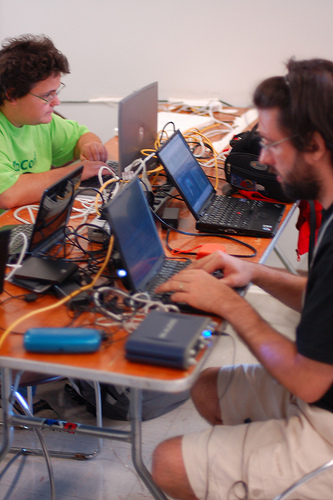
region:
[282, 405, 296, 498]
a man is wearing shorts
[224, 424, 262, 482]
a man is wearing shorts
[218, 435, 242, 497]
a man is wearing shorts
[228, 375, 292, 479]
a man is wearing shorts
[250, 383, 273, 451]
a man is wearing shorts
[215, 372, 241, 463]
a man is wearing shorts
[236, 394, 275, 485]
a man is wearing shorts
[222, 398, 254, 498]
a man is wearing shorts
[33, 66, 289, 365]
four laptops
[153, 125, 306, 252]
a black laptop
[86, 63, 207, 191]
a silver laptop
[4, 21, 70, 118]
a man wearing glasses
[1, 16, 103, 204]
a man wearing a green shirt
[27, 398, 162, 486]
a usa sticker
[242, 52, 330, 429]
a man wearing a black shirt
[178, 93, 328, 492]
a man wearing tan shorts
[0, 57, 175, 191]
a man on a laptop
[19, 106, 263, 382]
a wooden table with laptops on it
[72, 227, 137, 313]
lots of tangled computer cables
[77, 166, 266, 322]
black laptop computer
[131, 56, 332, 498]
man wearing khaki shorts and a black shirt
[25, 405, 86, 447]
"USA" label on table legs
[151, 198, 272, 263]
power adapter for a laptop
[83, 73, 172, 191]
silver laptop computer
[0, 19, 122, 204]
man with glasses wearing a green shirt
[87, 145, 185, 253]
surge protectors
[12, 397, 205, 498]
white tile floor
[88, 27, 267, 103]
bare white wall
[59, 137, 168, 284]
yellow black and white cords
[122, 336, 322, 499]
white shorts on a man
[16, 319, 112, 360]
blue case for glasses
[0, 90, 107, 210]
man wearing a green shirt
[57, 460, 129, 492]
white linoleum flooring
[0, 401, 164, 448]
metal bars under the table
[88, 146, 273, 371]
a laptop computer on the table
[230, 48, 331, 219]
a man with long hair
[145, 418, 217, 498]
a man's knee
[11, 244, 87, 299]
a black case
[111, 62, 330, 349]
man typing on a laptop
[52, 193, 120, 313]
a bunch of wires on a table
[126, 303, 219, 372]
a black modem on a table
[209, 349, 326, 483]
man wearing tan shorts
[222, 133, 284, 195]
a black bag on a table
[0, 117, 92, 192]
person wearing a green T-shirt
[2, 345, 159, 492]
a wood table with metal legs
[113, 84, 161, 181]
silver lid of a laptop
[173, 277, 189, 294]
a ring on a man's finger